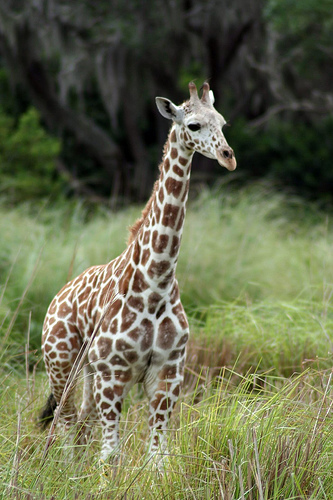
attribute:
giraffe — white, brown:
[39, 81, 241, 478]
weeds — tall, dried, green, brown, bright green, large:
[3, 190, 332, 358]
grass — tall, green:
[0, 304, 326, 498]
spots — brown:
[49, 173, 188, 437]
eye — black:
[184, 120, 203, 141]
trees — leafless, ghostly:
[0, 0, 332, 200]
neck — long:
[115, 147, 192, 283]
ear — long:
[155, 99, 176, 117]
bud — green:
[2, 232, 38, 339]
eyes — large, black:
[185, 118, 230, 135]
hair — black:
[40, 401, 50, 427]